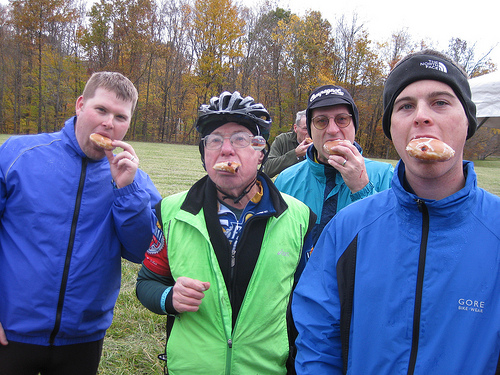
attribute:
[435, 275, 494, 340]
text — white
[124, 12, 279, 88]
tree — deciduous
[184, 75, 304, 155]
helmet — gray, safety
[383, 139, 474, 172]
danish — berry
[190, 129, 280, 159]
glasses — worn, paired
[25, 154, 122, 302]
windbreaker — blue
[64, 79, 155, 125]
haircut — tight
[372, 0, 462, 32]
sky — white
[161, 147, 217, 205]
field — harvest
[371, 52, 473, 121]
beanie — black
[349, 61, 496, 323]
man — eating, wearing, blue, here, present, holding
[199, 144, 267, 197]
doughnut — jelly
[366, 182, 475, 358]
jacket — blue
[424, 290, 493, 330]
logo — gore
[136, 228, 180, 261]
patch — colorful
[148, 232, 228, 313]
hand — grasping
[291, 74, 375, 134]
hat — black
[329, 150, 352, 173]
ring — silver, wedding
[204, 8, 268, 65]
trees — yellow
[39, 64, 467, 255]
men — five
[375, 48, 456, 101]
hat — wool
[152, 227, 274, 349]
windbreaker — green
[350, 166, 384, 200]
scratch — red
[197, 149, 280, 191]
pastry — filled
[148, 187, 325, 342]
vest — green